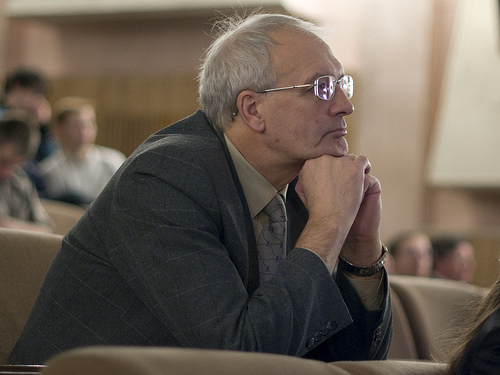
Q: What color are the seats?
A: Beige.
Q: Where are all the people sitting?
A: In a large room.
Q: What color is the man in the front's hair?
A: Gray.